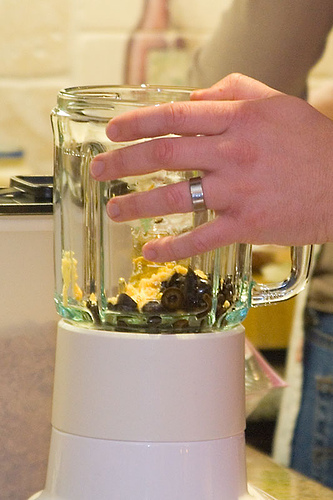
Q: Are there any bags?
A: Yes, there is a bag.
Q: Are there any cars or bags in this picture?
A: Yes, there is a bag.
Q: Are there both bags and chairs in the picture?
A: No, there is a bag but no chairs.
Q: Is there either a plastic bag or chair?
A: Yes, there is a plastic bag.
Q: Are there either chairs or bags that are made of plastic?
A: Yes, the bag is made of plastic.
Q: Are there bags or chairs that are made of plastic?
A: Yes, the bag is made of plastic.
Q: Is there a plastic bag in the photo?
A: Yes, there is a bag that is made of plastic.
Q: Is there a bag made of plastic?
A: Yes, there is a bag that is made of plastic.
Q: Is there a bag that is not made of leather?
A: Yes, there is a bag that is made of plastic.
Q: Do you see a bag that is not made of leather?
A: Yes, there is a bag that is made of plastic.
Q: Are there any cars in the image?
A: No, there are no cars.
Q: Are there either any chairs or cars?
A: No, there are no cars or chairs.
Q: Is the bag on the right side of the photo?
A: Yes, the bag is on the right of the image.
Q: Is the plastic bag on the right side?
A: Yes, the bag is on the right of the image.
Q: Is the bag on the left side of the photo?
A: No, the bag is on the right of the image.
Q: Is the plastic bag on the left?
A: No, the bag is on the right of the image.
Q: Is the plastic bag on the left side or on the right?
A: The bag is on the right of the image.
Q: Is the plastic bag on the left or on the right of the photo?
A: The bag is on the right of the image.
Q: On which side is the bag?
A: The bag is on the right of the image.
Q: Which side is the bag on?
A: The bag is on the right of the image.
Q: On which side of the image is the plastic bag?
A: The bag is on the right of the image.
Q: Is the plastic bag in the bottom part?
A: Yes, the bag is in the bottom of the image.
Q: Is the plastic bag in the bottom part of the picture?
A: Yes, the bag is in the bottom of the image.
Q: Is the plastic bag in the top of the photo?
A: No, the bag is in the bottom of the image.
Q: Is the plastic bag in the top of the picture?
A: No, the bag is in the bottom of the image.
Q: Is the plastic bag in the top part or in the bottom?
A: The bag is in the bottom of the image.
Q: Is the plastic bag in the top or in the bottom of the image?
A: The bag is in the bottom of the image.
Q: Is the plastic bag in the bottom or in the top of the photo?
A: The bag is in the bottom of the image.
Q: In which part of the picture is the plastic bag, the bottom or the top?
A: The bag is in the bottom of the image.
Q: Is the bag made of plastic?
A: Yes, the bag is made of plastic.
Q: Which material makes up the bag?
A: The bag is made of plastic.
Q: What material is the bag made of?
A: The bag is made of plastic.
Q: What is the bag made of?
A: The bag is made of plastic.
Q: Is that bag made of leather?
A: No, the bag is made of plastic.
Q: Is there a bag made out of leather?
A: No, there is a bag but it is made of plastic.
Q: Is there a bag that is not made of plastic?
A: No, there is a bag but it is made of plastic.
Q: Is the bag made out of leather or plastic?
A: The bag is made of plastic.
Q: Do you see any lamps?
A: No, there are no lamps.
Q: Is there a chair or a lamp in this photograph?
A: No, there are no lamps or chairs.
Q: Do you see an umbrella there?
A: No, there are no umbrellas.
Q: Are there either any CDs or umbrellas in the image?
A: No, there are no umbrellas or cds.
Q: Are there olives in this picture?
A: Yes, there are olives.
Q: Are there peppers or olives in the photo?
A: Yes, there are olives.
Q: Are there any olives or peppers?
A: Yes, there are olives.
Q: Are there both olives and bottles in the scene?
A: No, there are olives but no bottles.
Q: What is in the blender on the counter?
A: The olives are in the blender.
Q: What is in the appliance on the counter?
A: The olives are in the blender.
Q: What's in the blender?
A: The olives are in the blender.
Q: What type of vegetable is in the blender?
A: The vegetables are olives.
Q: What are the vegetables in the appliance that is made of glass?
A: The vegetables are olives.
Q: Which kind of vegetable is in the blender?
A: The vegetables are olives.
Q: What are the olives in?
A: The olives are in the blender.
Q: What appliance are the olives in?
A: The olives are in the blender.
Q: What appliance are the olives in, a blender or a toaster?
A: The olives are in a blender.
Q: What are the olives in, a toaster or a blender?
A: The olives are in a blender.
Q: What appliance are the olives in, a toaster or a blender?
A: The olives are in a blender.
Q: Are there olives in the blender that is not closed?
A: Yes, there are olives in the blender.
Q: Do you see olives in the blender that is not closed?
A: Yes, there are olives in the blender.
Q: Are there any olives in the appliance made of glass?
A: Yes, there are olives in the blender.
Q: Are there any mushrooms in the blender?
A: No, there are olives in the blender.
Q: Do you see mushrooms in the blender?
A: No, there are olives in the blender.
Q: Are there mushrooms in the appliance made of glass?
A: No, there are olives in the blender.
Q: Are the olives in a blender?
A: Yes, the olives are in a blender.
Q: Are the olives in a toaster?
A: No, the olives are in a blender.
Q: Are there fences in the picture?
A: No, there are no fences.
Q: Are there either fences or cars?
A: No, there are no fences or cars.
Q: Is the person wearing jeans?
A: Yes, the person is wearing jeans.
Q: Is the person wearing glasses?
A: No, the person is wearing jeans.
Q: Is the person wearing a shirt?
A: Yes, the person is wearing a shirt.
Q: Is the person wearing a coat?
A: No, the person is wearing a shirt.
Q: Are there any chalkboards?
A: No, there are no chalkboards.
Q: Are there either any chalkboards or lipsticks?
A: No, there are no chalkboards or lipsticks.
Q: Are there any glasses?
A: No, there are no glasses.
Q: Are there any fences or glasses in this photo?
A: No, there are no glasses or fences.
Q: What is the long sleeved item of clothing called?
A: The clothing item is a shirt.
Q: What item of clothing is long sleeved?
A: The clothing item is a shirt.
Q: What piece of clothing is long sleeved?
A: The clothing item is a shirt.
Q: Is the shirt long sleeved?
A: Yes, the shirt is long sleeved.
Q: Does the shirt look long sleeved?
A: Yes, the shirt is long sleeved.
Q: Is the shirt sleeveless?
A: No, the shirt is long sleeved.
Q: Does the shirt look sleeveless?
A: No, the shirt is long sleeved.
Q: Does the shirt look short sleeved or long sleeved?
A: The shirt is long sleeved.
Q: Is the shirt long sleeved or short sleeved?
A: The shirt is long sleeved.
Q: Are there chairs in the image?
A: No, there are no chairs.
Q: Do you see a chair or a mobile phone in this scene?
A: No, there are no chairs or cell phones.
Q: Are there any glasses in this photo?
A: No, there are no glasses.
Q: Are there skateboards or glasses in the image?
A: No, there are no glasses or skateboards.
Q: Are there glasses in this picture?
A: No, there are no glasses.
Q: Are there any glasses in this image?
A: No, there are no glasses.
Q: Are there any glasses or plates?
A: No, there are no glasses or plates.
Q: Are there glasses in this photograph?
A: No, there are no glasses.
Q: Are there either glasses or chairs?
A: No, there are no glasses or chairs.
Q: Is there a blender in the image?
A: Yes, there is a blender.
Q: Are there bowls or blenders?
A: Yes, there is a blender.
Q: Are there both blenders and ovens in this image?
A: No, there is a blender but no ovens.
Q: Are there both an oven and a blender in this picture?
A: No, there is a blender but no ovens.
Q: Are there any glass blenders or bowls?
A: Yes, there is a glass blender.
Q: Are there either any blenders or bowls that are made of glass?
A: Yes, the blender is made of glass.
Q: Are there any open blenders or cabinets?
A: Yes, there is an open blender.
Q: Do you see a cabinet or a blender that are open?
A: Yes, the blender is open.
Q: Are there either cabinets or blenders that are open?
A: Yes, the blender is open.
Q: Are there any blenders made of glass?
A: Yes, there is a blender that is made of glass.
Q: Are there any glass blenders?
A: Yes, there is a blender that is made of glass.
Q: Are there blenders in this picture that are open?
A: Yes, there is an open blender.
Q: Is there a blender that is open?
A: Yes, there is a blender that is open.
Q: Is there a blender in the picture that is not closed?
A: Yes, there is a open blender.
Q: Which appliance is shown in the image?
A: The appliance is a blender.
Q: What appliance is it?
A: The appliance is a blender.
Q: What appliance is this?
A: This is a blender.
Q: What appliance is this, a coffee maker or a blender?
A: This is a blender.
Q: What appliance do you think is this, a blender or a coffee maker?
A: This is a blender.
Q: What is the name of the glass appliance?
A: The appliance is a blender.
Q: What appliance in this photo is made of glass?
A: The appliance is a blender.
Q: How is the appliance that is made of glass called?
A: The appliance is a blender.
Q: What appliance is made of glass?
A: The appliance is a blender.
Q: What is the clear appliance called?
A: The appliance is a blender.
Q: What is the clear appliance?
A: The appliance is a blender.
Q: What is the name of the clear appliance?
A: The appliance is a blender.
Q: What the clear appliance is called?
A: The appliance is a blender.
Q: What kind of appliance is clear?
A: The appliance is a blender.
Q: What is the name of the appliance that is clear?
A: The appliance is a blender.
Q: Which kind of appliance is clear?
A: The appliance is a blender.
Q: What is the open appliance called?
A: The appliance is a blender.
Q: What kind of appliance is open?
A: The appliance is a blender.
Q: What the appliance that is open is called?
A: The appliance is a blender.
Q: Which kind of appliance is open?
A: The appliance is a blender.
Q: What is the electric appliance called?
A: The appliance is a blender.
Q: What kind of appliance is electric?
A: The appliance is a blender.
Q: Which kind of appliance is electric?
A: The appliance is a blender.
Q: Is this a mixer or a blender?
A: This is a blender.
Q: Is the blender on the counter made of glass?
A: Yes, the blender is made of glass.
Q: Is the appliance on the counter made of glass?
A: Yes, the blender is made of glass.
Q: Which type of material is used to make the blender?
A: The blender is made of glass.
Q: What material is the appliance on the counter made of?
A: The blender is made of glass.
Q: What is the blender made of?
A: The blender is made of glass.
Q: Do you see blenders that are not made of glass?
A: No, there is a blender but it is made of glass.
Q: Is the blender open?
A: Yes, the blender is open.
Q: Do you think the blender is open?
A: Yes, the blender is open.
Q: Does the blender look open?
A: Yes, the blender is open.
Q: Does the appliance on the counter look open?
A: Yes, the blender is open.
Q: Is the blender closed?
A: No, the blender is open.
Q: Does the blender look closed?
A: No, the blender is open.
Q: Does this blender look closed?
A: No, the blender is open.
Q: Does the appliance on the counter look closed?
A: No, the blender is open.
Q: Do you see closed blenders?
A: No, there is a blender but it is open.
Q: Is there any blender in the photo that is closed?
A: No, there is a blender but it is open.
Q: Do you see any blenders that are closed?
A: No, there is a blender but it is open.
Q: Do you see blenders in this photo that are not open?
A: No, there is a blender but it is open.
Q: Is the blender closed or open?
A: The blender is open.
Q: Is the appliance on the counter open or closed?
A: The blender is open.